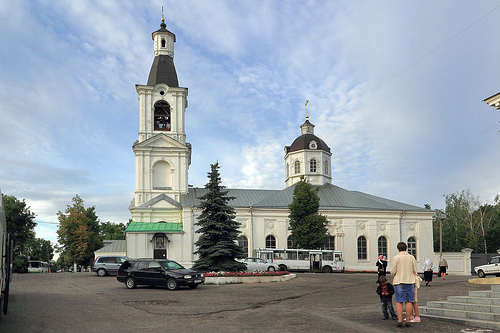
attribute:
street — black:
[39, 282, 97, 315]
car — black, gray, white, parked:
[106, 251, 212, 293]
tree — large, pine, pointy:
[190, 160, 247, 271]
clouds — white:
[272, 57, 273, 58]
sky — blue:
[35, 15, 89, 47]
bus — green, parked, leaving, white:
[248, 240, 325, 264]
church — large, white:
[205, 168, 488, 269]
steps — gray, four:
[434, 292, 491, 329]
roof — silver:
[333, 185, 390, 208]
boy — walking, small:
[374, 280, 393, 319]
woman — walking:
[373, 251, 392, 279]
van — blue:
[94, 257, 125, 275]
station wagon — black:
[134, 270, 176, 288]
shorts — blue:
[389, 281, 419, 307]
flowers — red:
[220, 267, 246, 277]